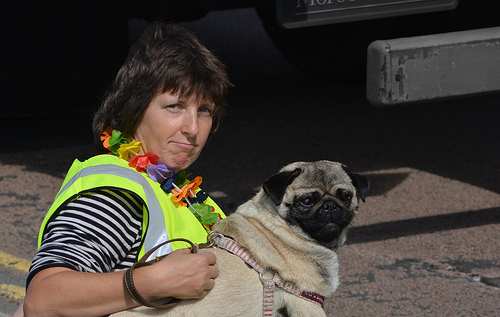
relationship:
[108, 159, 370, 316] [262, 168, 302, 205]
pug has ear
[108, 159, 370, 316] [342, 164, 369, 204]
pug has ear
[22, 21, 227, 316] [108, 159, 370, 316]
woman holding pug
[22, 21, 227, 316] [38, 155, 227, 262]
woman wearing vest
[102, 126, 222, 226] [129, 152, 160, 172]
necklace with flower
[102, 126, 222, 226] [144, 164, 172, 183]
necklace with flower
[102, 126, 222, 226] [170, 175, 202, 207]
necklace with flower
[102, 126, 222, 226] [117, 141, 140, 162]
necklace with flower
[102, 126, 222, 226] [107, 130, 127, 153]
necklace with flower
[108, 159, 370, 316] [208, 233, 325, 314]
pug wearing harness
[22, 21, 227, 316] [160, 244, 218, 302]
woman has hand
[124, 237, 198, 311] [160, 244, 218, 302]
leash in side of hand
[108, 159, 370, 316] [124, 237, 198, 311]
pug on end of leash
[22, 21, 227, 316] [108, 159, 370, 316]
woman with pug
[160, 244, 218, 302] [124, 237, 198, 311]
hand holding leash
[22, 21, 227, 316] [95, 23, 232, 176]
woman has head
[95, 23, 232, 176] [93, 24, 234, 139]
head has hair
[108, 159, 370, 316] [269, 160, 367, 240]
pug has head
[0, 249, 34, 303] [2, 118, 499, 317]
lines on top of pavement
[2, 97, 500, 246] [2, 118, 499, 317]
shadows on pavement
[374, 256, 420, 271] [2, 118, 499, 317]
stain on pavement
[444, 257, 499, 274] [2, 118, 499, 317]
stain on pavement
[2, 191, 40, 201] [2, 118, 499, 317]
stain on pavement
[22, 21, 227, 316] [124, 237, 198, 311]
woman holding leash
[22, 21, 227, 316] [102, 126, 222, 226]
woman wearing necklace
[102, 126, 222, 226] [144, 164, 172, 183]
necklace has flower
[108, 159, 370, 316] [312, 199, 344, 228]
pug has snout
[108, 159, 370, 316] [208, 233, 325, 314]
pug has harness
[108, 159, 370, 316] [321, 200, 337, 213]
pug has nose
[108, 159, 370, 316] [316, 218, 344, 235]
pug has mouth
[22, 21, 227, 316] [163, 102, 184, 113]
woman has eye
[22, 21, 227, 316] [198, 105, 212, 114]
woman has eye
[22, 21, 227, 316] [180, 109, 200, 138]
woman has nose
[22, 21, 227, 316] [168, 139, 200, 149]
woman has mouth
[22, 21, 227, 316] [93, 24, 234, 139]
woman has hair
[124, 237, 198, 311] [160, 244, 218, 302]
leash in middle of hand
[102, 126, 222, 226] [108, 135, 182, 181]
necklace around neck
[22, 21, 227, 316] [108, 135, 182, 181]
woman has neck